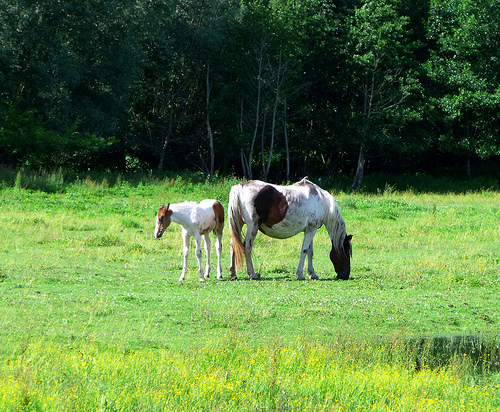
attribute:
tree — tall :
[240, 0, 336, 185]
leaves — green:
[0, 2, 496, 144]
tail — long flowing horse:
[227, 184, 243, 269]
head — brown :
[153, 207, 170, 238]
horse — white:
[215, 172, 364, 284]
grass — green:
[0, 176, 499, 408]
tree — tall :
[200, 4, 285, 166]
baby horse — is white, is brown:
[151, 196, 224, 280]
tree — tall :
[161, 14, 404, 178]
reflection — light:
[245, 277, 412, 325]